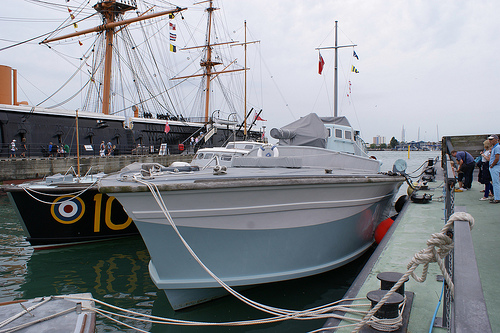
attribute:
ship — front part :
[109, 105, 405, 305]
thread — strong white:
[140, 178, 370, 319]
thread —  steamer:
[146, 195, 405, 327]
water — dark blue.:
[23, 253, 124, 288]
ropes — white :
[149, 190, 363, 319]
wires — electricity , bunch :
[45, 6, 293, 124]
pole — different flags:
[77, 5, 261, 152]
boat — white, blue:
[134, 159, 382, 285]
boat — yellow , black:
[14, 166, 128, 246]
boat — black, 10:
[11, 163, 127, 249]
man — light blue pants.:
[481, 134, 484, 210]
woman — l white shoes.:
[479, 151, 484, 207]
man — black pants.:
[464, 141, 482, 191]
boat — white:
[108, 100, 411, 300]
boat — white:
[88, 117, 395, 303]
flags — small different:
[316, 43, 363, 83]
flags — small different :
[282, 35, 374, 88]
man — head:
[460, 141, 470, 154]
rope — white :
[142, 180, 372, 314]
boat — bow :
[103, 133, 420, 286]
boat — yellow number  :
[84, 194, 132, 240]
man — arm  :
[457, 144, 476, 189]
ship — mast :
[128, 92, 424, 300]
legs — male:
[457, 160, 474, 190]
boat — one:
[99, 138, 403, 302]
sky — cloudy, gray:
[367, 22, 437, 107]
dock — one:
[457, 181, 498, 297]